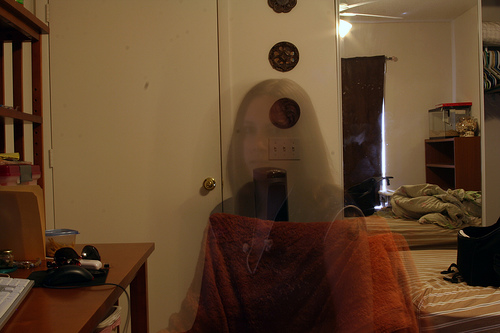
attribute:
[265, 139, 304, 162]
switches — white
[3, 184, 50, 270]
file — brown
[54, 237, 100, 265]
sunglasses — white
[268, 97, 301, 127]
circle — black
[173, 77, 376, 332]
reflection — clear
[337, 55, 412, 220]
curtains — brown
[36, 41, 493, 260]
wall — white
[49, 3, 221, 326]
door — white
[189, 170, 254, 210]
knob — white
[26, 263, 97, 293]
mouse — white